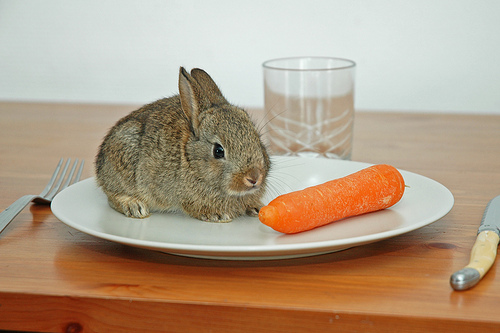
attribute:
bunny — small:
[97, 66, 272, 225]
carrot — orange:
[259, 163, 406, 233]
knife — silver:
[452, 194, 498, 294]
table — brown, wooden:
[0, 248, 500, 325]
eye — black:
[200, 126, 231, 174]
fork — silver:
[11, 161, 97, 254]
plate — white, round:
[25, 122, 499, 273]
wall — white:
[0, 0, 499, 114]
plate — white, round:
[49, 154, 455, 261]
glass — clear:
[264, 55, 354, 160]